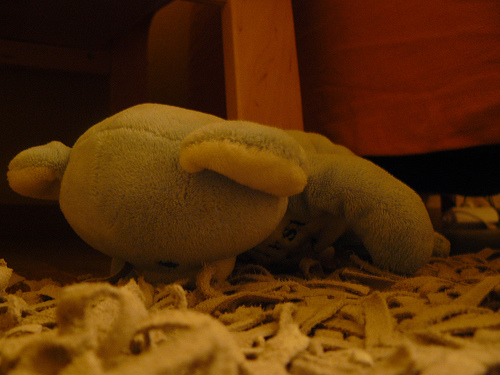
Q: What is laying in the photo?
A: A stuffed toy.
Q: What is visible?
A: A stuffed toy.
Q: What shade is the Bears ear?
A: Pink.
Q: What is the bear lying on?
A: A bed.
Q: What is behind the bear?
A: Wooden furniture.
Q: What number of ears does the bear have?
A: Two.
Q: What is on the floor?
A: Teddy bear.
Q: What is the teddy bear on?
A: The floor.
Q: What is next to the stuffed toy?
A: A bed.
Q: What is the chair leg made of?
A: Wood.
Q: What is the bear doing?
A: Lying face down.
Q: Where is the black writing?
A: On the bear.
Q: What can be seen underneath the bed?
A: Wires.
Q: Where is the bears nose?
A: On the floor.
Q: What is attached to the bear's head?
A: An ear.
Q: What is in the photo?
A: Teddy bear.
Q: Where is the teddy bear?
A: On the ground.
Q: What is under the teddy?
A: The ground.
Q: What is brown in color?
A: The object next to the bear.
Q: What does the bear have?
A: Ears.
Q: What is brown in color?
A: The wood.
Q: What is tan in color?
A: The rug.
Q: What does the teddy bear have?
A: Arms.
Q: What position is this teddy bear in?
A: Face down.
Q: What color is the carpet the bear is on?
A: Beige.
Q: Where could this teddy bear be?
A: A bedroom.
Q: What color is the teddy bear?
A: Grey.